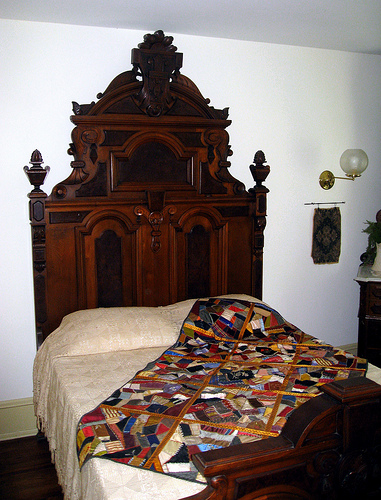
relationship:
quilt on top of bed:
[76, 296, 369, 485] [23, 29, 381, 500]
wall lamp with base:
[319, 147, 370, 189] [318, 169, 363, 190]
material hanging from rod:
[310, 206, 342, 265] [303, 200, 345, 206]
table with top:
[353, 262, 380, 367] [352, 264, 380, 283]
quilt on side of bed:
[76, 296, 369, 485] [23, 29, 381, 500]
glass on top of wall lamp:
[339, 149, 368, 176] [319, 147, 370, 189]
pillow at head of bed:
[62, 306, 180, 356] [23, 29, 381, 500]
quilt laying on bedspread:
[76, 296, 369, 485] [32, 292, 381, 500]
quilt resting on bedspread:
[76, 296, 369, 485] [32, 292, 381, 500]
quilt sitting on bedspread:
[76, 296, 369, 485] [32, 292, 381, 500]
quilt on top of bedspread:
[76, 296, 369, 485] [32, 292, 381, 500]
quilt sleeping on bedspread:
[76, 296, 369, 485] [32, 292, 381, 500]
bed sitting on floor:
[23, 29, 381, 500] [0, 434, 66, 499]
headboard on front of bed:
[23, 29, 270, 351] [23, 29, 381, 500]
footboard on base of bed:
[178, 375, 381, 500] [23, 29, 381, 500]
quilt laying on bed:
[76, 296, 369, 485] [23, 29, 381, 500]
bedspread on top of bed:
[32, 292, 381, 500] [23, 29, 381, 500]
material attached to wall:
[310, 206, 342, 265] [1, 19, 380, 441]